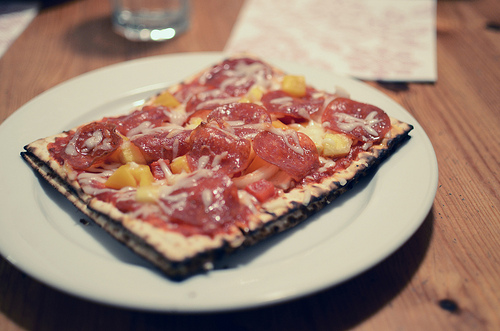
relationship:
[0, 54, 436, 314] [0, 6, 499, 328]
plate above table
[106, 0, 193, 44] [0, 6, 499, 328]
glass on table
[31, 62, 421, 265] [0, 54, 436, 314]
pizza on plate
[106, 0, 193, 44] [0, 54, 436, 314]
glass next to plate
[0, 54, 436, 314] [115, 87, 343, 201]
plate holding pizza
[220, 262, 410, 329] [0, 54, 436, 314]
shadow of a plate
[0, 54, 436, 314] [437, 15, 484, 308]
plate on a table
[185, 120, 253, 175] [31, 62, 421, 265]
topping on pizza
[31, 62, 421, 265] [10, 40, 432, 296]
pizza on plate